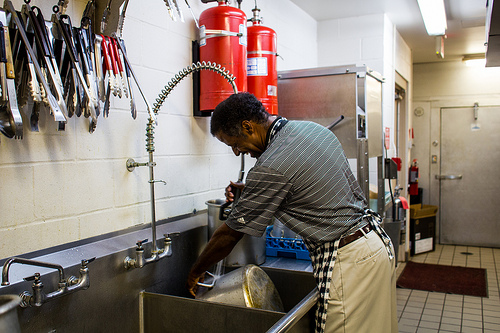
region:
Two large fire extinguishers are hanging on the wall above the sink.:
[192, 0, 282, 125]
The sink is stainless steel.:
[0, 200, 324, 331]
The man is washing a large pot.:
[188, 261, 282, 314]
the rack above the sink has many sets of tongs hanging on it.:
[0, 0, 213, 145]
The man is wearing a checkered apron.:
[261, 109, 393, 331]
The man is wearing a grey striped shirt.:
[221, 117, 376, 248]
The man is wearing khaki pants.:
[314, 222, 403, 331]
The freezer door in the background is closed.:
[436, 102, 499, 250]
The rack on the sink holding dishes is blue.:
[264, 222, 316, 266]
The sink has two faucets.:
[3, 229, 183, 304]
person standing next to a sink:
[178, 85, 405, 331]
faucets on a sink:
[118, 224, 190, 274]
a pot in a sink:
[183, 256, 300, 328]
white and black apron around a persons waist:
[292, 208, 349, 332]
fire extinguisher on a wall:
[403, 153, 426, 203]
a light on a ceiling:
[403, 0, 467, 45]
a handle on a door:
[428, 164, 474, 199]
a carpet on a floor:
[387, 257, 493, 307]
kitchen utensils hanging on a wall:
[0, 4, 140, 147]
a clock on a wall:
[405, 100, 432, 122]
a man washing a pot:
[198, 90, 415, 315]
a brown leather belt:
[339, 229, 364, 243]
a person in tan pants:
[337, 248, 404, 331]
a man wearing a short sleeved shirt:
[213, 115, 365, 227]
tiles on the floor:
[416, 300, 466, 328]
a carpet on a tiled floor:
[400, 250, 492, 304]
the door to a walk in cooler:
[437, 100, 499, 227]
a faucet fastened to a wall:
[123, 142, 157, 174]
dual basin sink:
[10, 246, 307, 331]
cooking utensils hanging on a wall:
[3, 5, 135, 115]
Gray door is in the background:
[430, 93, 496, 265]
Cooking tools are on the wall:
[1, 2, 160, 143]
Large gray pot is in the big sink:
[187, 254, 302, 331]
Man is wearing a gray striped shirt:
[218, 116, 400, 268]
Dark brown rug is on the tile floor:
[396, 251, 492, 306]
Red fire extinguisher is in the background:
[398, 148, 426, 203]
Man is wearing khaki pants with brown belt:
[300, 217, 410, 327]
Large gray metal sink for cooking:
[1, 195, 376, 331]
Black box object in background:
[399, 212, 442, 258]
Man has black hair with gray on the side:
[201, 86, 326, 200]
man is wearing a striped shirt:
[207, 87, 379, 251]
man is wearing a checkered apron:
[262, 113, 397, 332]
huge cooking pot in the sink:
[191, 260, 286, 320]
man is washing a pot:
[185, 88, 401, 331]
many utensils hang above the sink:
[0, 0, 155, 142]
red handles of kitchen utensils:
[97, 30, 127, 77]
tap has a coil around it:
[146, 60, 250, 196]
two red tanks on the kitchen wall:
[194, 1, 281, 123]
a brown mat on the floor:
[389, 250, 492, 304]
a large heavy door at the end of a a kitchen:
[436, 101, 498, 246]